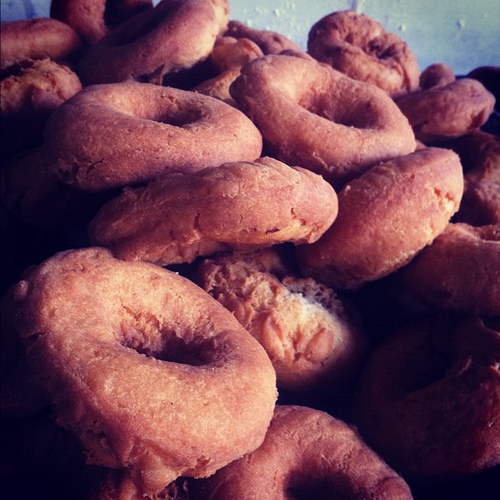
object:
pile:
[0, 0, 500, 490]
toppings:
[271, 261, 352, 338]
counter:
[247, 4, 478, 80]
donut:
[103, 162, 349, 252]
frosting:
[250, 244, 359, 349]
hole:
[120, 313, 234, 373]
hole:
[276, 458, 371, 500]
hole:
[263, 249, 356, 323]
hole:
[112, 90, 212, 135]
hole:
[344, 31, 394, 65]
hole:
[474, 225, 496, 242]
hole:
[3, 52, 34, 75]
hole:
[104, 3, 137, 43]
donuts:
[205, 404, 415, 500]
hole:
[291, 79, 382, 138]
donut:
[4, 405, 94, 495]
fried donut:
[27, 246, 274, 492]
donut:
[59, 73, 260, 184]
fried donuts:
[308, 141, 464, 286]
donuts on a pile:
[5, 7, 493, 499]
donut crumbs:
[227, 16, 314, 50]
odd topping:
[281, 272, 353, 353]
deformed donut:
[305, 9, 422, 90]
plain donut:
[230, 50, 417, 184]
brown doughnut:
[86, 4, 239, 84]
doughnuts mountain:
[8, 1, 487, 496]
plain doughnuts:
[58, 76, 348, 268]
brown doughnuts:
[229, 52, 465, 281]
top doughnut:
[80, 4, 230, 81]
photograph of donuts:
[1, 4, 497, 486]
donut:
[23, 241, 290, 471]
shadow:
[326, 259, 448, 362]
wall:
[225, 0, 500, 74]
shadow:
[156, 336, 210, 374]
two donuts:
[227, 10, 431, 179]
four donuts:
[69, 52, 467, 277]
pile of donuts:
[7, 9, 498, 491]